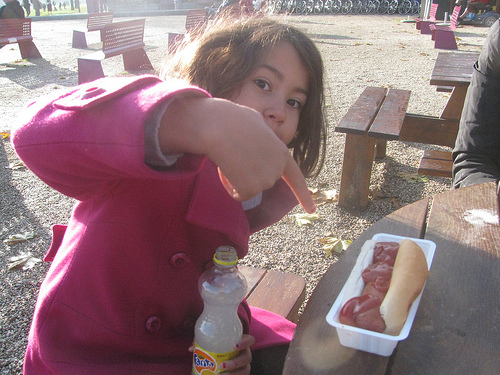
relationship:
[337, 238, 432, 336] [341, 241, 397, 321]
hotdog with ketchup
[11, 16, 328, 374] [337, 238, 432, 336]
girl with hotdog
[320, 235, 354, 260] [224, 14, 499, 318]
leaves on ground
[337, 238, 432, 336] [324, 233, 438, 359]
hotdog in container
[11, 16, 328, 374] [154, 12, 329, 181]
girl with hair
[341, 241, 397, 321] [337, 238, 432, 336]
ketchup on hotdog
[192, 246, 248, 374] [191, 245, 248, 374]
fanta in bottle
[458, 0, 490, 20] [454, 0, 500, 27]
person on scooter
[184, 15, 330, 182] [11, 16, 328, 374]
head on girl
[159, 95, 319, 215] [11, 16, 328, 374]
hand of girl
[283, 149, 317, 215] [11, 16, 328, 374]
finger of girl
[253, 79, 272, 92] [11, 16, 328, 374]
eye of girl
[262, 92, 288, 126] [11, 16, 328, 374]
nose of girl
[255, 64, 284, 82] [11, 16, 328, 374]
eyebrow of girl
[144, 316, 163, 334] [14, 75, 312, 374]
button on coat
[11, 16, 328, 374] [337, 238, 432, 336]
girl pointing at hotdog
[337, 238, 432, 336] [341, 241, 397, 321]
hotdog and ketchup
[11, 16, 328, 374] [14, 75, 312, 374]
girl wearing coat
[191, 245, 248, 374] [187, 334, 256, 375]
lemonade in hand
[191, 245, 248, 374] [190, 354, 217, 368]
bottle containing fanta